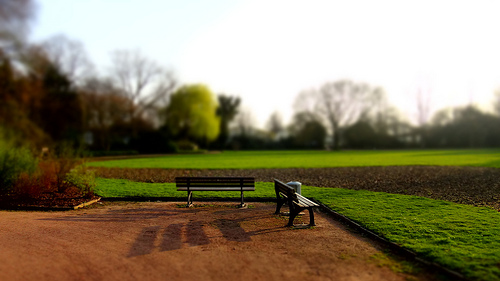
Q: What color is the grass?
A: Green.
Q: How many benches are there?
A: Two.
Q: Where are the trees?
A: Around the field.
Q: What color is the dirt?
A: Brown.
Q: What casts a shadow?
A: The benches.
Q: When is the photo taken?
A: Daytime.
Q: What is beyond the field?
A: Trees.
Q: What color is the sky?
A: Blue.